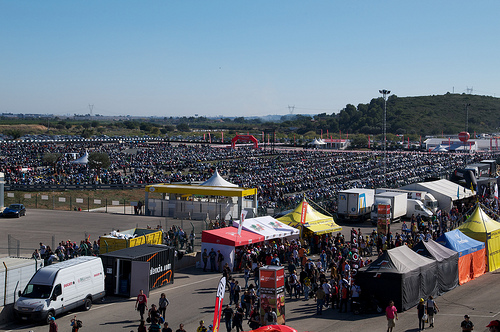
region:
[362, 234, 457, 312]
Two black tents side by side.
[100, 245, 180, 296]
Black storage container with orange stripe and white letters.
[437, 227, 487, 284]
Blue and orange tent.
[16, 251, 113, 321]
White truck with grey bottom.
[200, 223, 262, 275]
White tent with red top.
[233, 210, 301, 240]
White tent with two red, green and white logos on it.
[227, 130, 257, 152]
Red arches in front of large lot.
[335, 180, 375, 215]
White truck with blue and yellow design.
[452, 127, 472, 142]
Red balloon with white stripe in center.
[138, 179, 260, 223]
Long yellow tent top in front of white tent.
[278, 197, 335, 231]
a yellow and red tent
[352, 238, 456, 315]
a couple of black tents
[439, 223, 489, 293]
a orange and blue tent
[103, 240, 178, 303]
a black and orange trailer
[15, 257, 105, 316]
a white van on the road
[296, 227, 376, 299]
a crowd og people walking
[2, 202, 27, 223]
a car on a parking lot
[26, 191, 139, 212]
white signs on a fence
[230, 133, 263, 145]
a bright red arch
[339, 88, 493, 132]
a green grassy hill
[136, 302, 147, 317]
leg of a person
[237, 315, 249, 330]
leg of a person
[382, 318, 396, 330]
leg of a person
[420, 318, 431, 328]
leg of a person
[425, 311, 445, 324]
leg of a person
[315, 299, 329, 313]
leg of a person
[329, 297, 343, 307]
leg of a person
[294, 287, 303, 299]
leg of a person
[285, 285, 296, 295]
leg of a person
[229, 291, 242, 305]
leg of a person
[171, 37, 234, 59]
Part of the sky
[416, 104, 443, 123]
Part of the green hill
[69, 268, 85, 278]
Part of the white van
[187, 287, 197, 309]
Part of the street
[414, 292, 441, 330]
Two people walking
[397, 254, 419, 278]
Part of the tent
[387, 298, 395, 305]
The head of the person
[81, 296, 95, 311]
The back tire of the van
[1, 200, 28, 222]
A black car in distance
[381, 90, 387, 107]
Part of the light pole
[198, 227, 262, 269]
a white and red pop up tent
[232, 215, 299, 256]
a white pop up tent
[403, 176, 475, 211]
a white pop up tent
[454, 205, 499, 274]
a yellow pop up tent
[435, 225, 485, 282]
a blue and orange pop up tent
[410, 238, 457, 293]
a black pop up tent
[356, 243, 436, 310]
a black pop up tent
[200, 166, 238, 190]
a white pop up tent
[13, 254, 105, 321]
a white commercial van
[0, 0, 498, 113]
a hazy blue sky